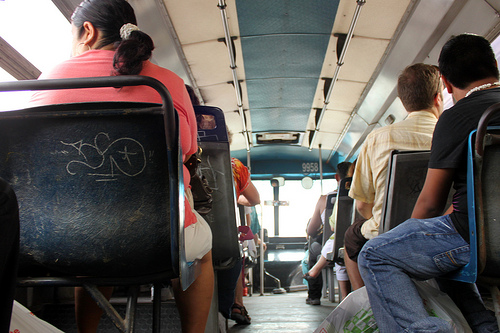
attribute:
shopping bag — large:
[311, 283, 381, 330]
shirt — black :
[428, 97, 495, 167]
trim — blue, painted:
[229, 146, 339, 173]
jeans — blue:
[339, 198, 491, 332]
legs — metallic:
[88, 282, 143, 326]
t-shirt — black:
[422, 91, 499, 253]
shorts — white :
[185, 205, 215, 262]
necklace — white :
[462, 78, 497, 105]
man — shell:
[354, 30, 498, 330]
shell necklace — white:
[457, 79, 499, 95]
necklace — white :
[433, 73, 497, 92]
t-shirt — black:
[428, 104, 483, 176]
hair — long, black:
[66, 0, 168, 81]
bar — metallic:
[215, 1, 255, 150]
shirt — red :
[15, 51, 203, 230]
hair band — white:
[118, 20, 140, 38]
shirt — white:
[349, 109, 446, 224]